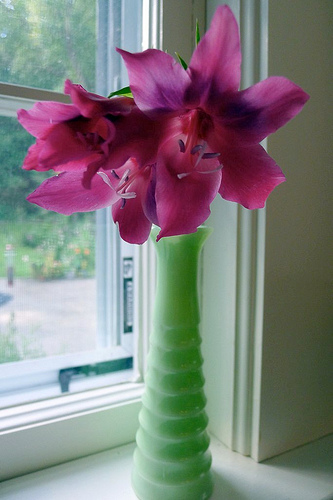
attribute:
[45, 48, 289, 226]
petals — pink, purple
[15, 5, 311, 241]
flowers — inside, pink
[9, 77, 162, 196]
flower — pink, purple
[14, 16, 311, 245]
flower — purple, pink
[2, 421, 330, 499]
window ledge — white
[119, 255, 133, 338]
sticker — Black, white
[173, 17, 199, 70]
leaves — green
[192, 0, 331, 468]
wall — white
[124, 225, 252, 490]
vase — neon, green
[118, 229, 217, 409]
vase — Tall, green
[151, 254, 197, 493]
vase — green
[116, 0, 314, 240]
flower — pink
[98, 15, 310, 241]
flower — pink, purple, bright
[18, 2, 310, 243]
pink flowers — Small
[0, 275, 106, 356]
sidewalk — Brown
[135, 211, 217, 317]
vase — green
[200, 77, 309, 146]
petal — flower, pink, purple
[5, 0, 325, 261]
flower — pink, purple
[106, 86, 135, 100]
leaves — green 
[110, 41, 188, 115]
petals — pink, purple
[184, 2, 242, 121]
petals — pink, purple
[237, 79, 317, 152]
petals — pink, purple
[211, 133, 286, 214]
petals — pink, purple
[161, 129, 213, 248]
petals — pink, purple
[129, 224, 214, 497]
vase — thin, green, glass, light green, tall, light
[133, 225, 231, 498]
glass — light, green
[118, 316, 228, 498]
ripples — Green